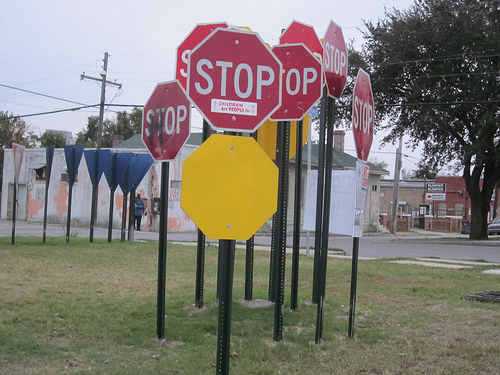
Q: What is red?
A: Signs.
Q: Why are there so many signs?
A: It is a yard of signs.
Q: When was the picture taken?
A: Daytime.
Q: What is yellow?
A: The octagon.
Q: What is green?
A: Grass.